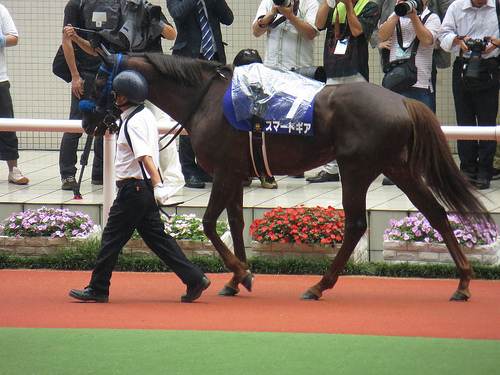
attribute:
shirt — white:
[102, 98, 167, 185]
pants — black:
[87, 174, 202, 293]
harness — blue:
[80, 52, 120, 124]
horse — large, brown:
[82, 40, 478, 300]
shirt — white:
[110, 103, 163, 179]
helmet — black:
[112, 70, 151, 105]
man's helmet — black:
[111, 62, 148, 100]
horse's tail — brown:
[403, 92, 498, 226]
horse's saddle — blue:
[221, 54, 320, 135]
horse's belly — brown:
[223, 130, 335, 178]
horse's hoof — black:
[298, 280, 326, 306]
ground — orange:
[1, 264, 499, 344]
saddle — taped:
[226, 57, 311, 137]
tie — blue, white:
[193, 2, 219, 64]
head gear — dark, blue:
[111, 70, 149, 100]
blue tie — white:
[190, 1, 225, 64]